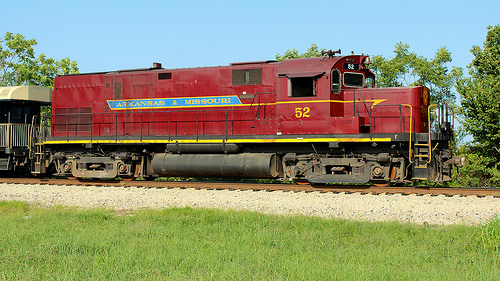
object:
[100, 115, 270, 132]
pain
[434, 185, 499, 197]
tracks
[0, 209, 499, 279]
grass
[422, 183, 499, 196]
tracks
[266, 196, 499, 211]
dirt and gravel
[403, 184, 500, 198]
steel tracks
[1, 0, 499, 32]
blue sky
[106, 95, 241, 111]
business name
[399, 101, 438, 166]
yellow handrails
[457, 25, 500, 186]
green trees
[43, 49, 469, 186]
train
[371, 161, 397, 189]
train wheels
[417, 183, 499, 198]
track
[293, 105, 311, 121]
id number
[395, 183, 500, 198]
track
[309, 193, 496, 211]
gravel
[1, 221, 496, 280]
grass field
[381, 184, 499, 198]
tracks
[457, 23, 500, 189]
trees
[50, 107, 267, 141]
safety rail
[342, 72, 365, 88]
front windshield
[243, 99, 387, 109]
pin stripe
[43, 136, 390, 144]
pin stripe